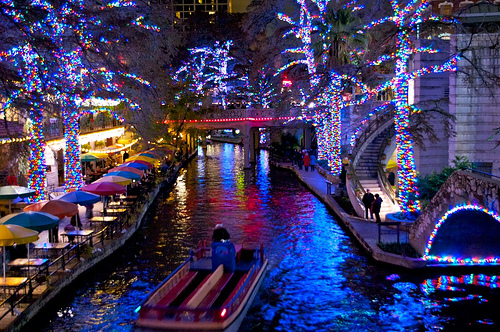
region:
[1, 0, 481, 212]
trees with blue green and red lights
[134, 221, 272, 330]
empty boat on canal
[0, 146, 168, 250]
yellow blue red and green umbrellas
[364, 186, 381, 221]
people walking next to canal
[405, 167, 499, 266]
lit bridge over canal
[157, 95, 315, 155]
bridge with red light over canal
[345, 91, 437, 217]
white curved stairs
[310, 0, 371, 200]
palm tree next to canal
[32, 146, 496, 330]
dark water with reflections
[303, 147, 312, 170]
lady in red coat walking next to canal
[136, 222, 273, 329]
A small boat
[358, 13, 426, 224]
Two people standing next to a tree lit with small colorful lights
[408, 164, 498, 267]
the entrance to a tunnel lit with small colorful lights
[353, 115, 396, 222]
two people standing at the bottom of a winding staircase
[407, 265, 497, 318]
reflection of colorful lights in the water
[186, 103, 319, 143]
A bridge lit with small red lights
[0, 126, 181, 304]
a row of tables with colorful umbrellas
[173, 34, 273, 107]
a group of trees light with colorful lights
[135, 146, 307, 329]
a small boat traveling through a canal of water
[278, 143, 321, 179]
a group of people walking on a sidewalk by a canal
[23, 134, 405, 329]
winding canal at night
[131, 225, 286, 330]
small boat in a canal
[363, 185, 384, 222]
two people at the base of a stairway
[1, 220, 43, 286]
yellow umbrella nearest to the camera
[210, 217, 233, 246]
person operating the boat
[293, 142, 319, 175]
people walking near a crosswalk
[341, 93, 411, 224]
large curved stairway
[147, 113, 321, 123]
red lights on the crosswalk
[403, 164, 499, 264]
bridge decorated with lights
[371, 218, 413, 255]
handrail near bridge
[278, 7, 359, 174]
Lights on a tree.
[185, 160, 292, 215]
Lights reflected in the water.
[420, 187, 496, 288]
Bridge with lights strung underneath.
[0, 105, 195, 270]
Umbrellas next to the water.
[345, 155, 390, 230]
People standing near the stairs.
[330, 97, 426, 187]
A set of stairs on a building.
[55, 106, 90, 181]
Lights on a tree trunk.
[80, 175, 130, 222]
A table under an umbrella.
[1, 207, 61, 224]
A blue umbrella.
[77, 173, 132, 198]
A red umbrella.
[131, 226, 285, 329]
A boat in the water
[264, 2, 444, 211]
three trees on the right with lights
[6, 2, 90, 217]
two trees on the left with lights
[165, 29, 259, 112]
Two trees in the background with lights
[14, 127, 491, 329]
water reflecting christmas lights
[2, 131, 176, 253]
A bunch of colorful umbrellas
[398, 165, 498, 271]
A bridge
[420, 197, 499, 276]
a bunch of lights under the bridge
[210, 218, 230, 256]
an old man driving the boat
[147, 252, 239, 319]
benches on the boat